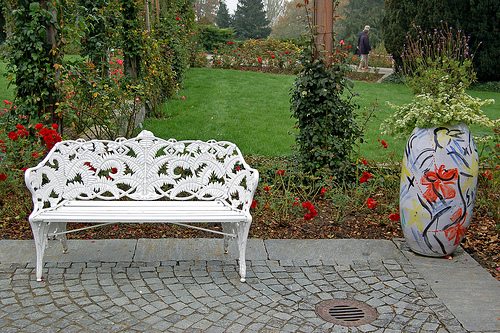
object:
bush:
[2, 109, 62, 237]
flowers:
[390, 19, 483, 86]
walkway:
[345, 66, 393, 74]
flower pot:
[399, 121, 478, 257]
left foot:
[32, 229, 48, 282]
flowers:
[388, 213, 400, 221]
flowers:
[304, 214, 311, 221]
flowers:
[321, 188, 326, 196]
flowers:
[264, 202, 271, 209]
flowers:
[277, 169, 284, 176]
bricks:
[244, 297, 262, 309]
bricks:
[149, 281, 165, 292]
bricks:
[38, 302, 59, 312]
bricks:
[377, 304, 392, 314]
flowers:
[47, 143, 54, 150]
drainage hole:
[314, 299, 376, 327]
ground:
[0, 54, 499, 331]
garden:
[1, 10, 498, 236]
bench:
[24, 129, 259, 283]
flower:
[367, 198, 377, 208]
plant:
[382, 15, 496, 124]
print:
[411, 153, 465, 253]